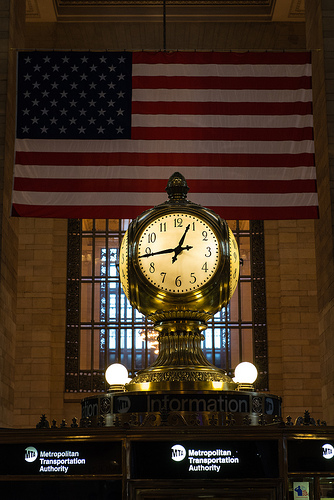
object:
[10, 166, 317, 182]
stripes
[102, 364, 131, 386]
light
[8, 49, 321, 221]
flag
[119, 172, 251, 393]
clock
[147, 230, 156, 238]
black numbers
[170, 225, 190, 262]
hour hand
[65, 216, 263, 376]
bars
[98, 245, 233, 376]
window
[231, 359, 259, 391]
light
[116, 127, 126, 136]
white stars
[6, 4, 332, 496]
station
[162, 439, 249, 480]
sign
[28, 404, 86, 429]
chandelier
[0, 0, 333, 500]
background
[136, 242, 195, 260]
hands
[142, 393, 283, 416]
letters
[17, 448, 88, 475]
letters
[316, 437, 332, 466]
sticker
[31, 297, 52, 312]
brick work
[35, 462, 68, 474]
letters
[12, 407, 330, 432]
metal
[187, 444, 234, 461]
metropolitan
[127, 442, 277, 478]
black background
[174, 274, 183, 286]
6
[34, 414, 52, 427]
design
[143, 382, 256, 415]
information